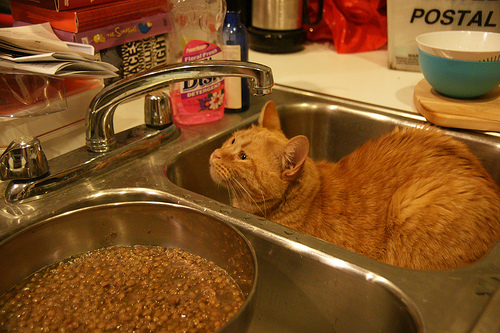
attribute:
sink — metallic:
[4, 75, 497, 331]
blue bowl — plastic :
[415, 49, 499, 99]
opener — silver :
[2, 132, 52, 185]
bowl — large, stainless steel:
[0, 198, 262, 331]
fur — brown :
[207, 99, 497, 272]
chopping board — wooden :
[268, 19, 495, 146]